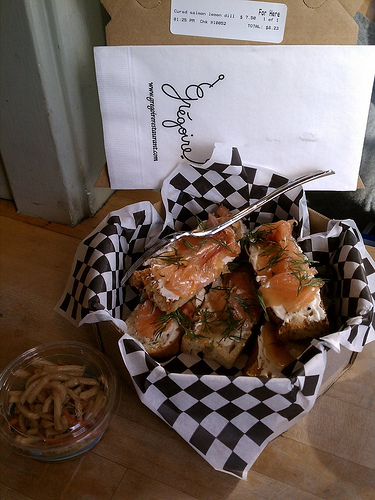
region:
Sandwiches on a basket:
[74, 155, 365, 423]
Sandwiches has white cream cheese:
[138, 209, 323, 379]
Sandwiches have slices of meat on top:
[124, 205, 329, 383]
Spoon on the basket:
[108, 159, 344, 279]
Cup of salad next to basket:
[0, 336, 114, 467]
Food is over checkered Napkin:
[64, 143, 370, 451]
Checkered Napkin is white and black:
[49, 156, 372, 481]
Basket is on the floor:
[9, 212, 369, 494]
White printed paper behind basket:
[87, 36, 370, 189]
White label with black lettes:
[165, 0, 291, 45]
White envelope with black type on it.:
[92, 43, 373, 190]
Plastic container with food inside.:
[1, 341, 117, 457]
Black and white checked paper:
[53, 138, 374, 479]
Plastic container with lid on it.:
[1, 337, 119, 462]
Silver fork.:
[117, 166, 333, 286]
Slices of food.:
[125, 199, 331, 374]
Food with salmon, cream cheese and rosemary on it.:
[128, 179, 329, 373]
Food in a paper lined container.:
[54, 142, 374, 477]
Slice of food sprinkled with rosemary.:
[242, 217, 332, 333]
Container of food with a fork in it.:
[56, 142, 374, 478]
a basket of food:
[108, 154, 357, 377]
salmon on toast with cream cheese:
[106, 202, 343, 371]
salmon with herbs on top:
[117, 200, 368, 392]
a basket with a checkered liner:
[54, 186, 356, 448]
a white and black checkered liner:
[57, 189, 369, 486]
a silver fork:
[97, 118, 349, 347]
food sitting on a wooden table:
[30, 150, 366, 475]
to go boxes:
[64, 0, 373, 210]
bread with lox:
[98, 208, 340, 407]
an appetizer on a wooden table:
[6, 305, 141, 487]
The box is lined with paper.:
[72, 161, 374, 413]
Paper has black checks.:
[50, 126, 374, 483]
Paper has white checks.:
[50, 132, 373, 485]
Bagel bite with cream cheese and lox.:
[247, 221, 338, 350]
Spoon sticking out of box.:
[110, 156, 337, 299]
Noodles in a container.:
[0, 338, 123, 471]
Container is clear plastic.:
[1, 333, 124, 472]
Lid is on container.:
[0, 335, 126, 468]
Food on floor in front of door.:
[0, 137, 374, 481]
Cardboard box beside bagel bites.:
[1, 0, 373, 189]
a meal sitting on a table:
[7, 0, 355, 474]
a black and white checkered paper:
[203, 420, 245, 464]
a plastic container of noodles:
[3, 337, 124, 465]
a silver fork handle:
[220, 164, 339, 214]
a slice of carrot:
[66, 407, 75, 431]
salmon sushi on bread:
[267, 231, 313, 310]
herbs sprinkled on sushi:
[216, 312, 241, 335]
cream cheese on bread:
[307, 305, 319, 317]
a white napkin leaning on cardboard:
[121, 42, 357, 174]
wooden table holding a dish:
[283, 431, 349, 486]